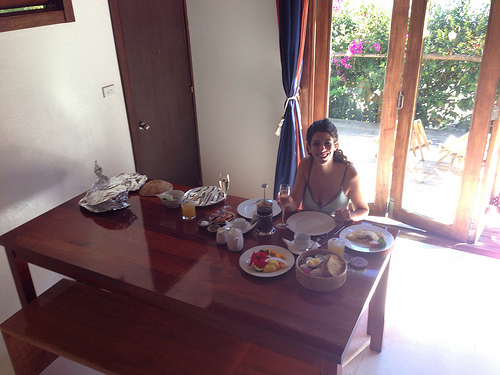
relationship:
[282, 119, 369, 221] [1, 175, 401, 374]
woman sitting at table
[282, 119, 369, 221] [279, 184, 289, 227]
woman holding glass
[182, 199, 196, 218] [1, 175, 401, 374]
orange juice on top of table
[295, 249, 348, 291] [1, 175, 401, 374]
basket on top of table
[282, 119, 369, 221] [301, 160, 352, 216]
woman wearing tank top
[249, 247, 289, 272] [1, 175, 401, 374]
food on top of table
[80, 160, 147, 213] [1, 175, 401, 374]
foil on top of table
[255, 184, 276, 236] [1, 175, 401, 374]
coffee press on top of table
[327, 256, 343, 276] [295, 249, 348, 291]
bread inside basket